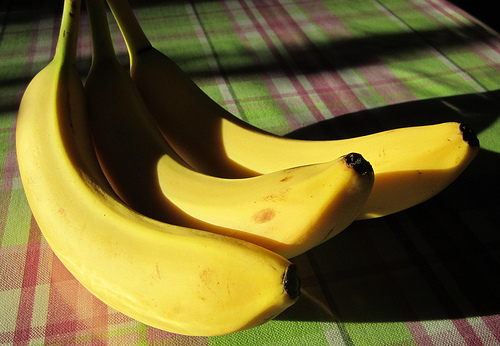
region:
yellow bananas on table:
[37, 28, 402, 299]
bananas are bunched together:
[17, 34, 377, 332]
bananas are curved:
[18, 40, 400, 327]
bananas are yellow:
[41, 51, 391, 297]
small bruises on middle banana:
[254, 162, 294, 232]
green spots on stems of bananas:
[49, 1, 176, 83]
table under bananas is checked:
[198, 24, 391, 121]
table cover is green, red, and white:
[176, 15, 403, 142]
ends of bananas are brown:
[305, 143, 460, 258]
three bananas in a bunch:
[42, 13, 433, 324]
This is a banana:
[122, 25, 480, 227]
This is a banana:
[18, 44, 312, 342]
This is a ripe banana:
[125, 25, 496, 205]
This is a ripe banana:
[70, 51, 391, 256]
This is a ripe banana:
[5, 64, 302, 344]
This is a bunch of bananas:
[18, 1, 498, 343]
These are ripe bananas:
[10, 11, 487, 343]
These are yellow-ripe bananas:
[18, 8, 483, 340]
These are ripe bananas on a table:
[2, 1, 494, 343]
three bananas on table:
[15, 8, 393, 308]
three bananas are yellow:
[25, 28, 369, 289]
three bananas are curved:
[3, 65, 369, 289]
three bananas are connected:
[67, 4, 424, 332]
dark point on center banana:
[285, 136, 402, 187]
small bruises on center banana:
[238, 171, 305, 216]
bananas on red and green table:
[8, 41, 398, 343]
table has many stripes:
[195, 18, 322, 110]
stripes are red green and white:
[218, 26, 466, 105]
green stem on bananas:
[32, 22, 140, 57]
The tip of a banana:
[450, 113, 481, 156]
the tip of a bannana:
[334, 146, 373, 188]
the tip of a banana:
[258, 254, 312, 321]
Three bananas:
[19, 12, 489, 333]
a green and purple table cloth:
[225, 7, 480, 92]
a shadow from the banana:
[349, 221, 481, 300]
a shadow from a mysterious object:
[242, 12, 475, 84]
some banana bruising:
[232, 202, 288, 224]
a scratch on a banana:
[57, 76, 83, 146]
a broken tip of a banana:
[128, 42, 160, 64]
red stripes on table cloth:
[231, 0, 386, 120]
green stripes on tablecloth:
[148, 8, 301, 139]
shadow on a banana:
[50, 38, 259, 259]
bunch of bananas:
[27, 10, 479, 344]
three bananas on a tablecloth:
[2, 9, 497, 337]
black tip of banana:
[341, 147, 381, 191]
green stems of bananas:
[56, 2, 146, 72]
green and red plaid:
[223, 11, 413, 133]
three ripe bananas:
[20, 10, 498, 332]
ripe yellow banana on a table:
[24, 55, 360, 328]